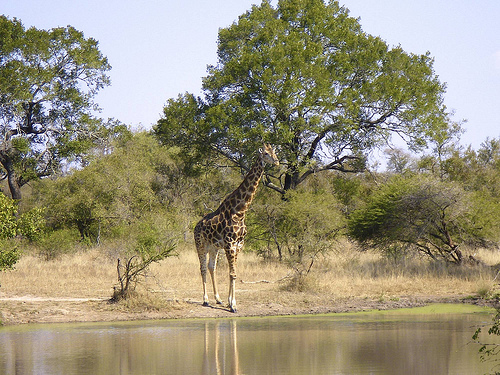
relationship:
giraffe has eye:
[192, 145, 282, 314] [264, 151, 268, 155]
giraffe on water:
[192, 145, 282, 314] [32, 321, 492, 372]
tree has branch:
[338, 175, 485, 272] [403, 217, 442, 240]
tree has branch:
[338, 175, 485, 272] [401, 235, 431, 255]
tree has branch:
[338, 175, 485, 272] [440, 211, 454, 239]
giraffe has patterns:
[192, 145, 282, 314] [209, 207, 244, 255]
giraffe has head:
[192, 145, 282, 314] [257, 140, 280, 166]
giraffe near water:
[192, 145, 282, 314] [32, 321, 492, 372]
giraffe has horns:
[192, 145, 282, 314] [252, 139, 282, 153]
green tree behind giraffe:
[148, 0, 459, 200] [192, 145, 282, 314]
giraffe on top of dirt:
[192, 145, 282, 314] [158, 295, 203, 322]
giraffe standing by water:
[192, 145, 282, 314] [0, 311, 499, 373]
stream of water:
[3, 297, 494, 368] [0, 302, 497, 374]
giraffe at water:
[147, 101, 329, 333] [3, 297, 496, 371]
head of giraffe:
[248, 139, 283, 169] [192, 145, 282, 314]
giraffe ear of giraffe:
[252, 145, 266, 154] [192, 145, 282, 314]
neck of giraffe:
[219, 157, 266, 215] [192, 145, 282, 314]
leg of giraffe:
[224, 240, 236, 310] [192, 145, 282, 314]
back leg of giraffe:
[207, 252, 220, 304] [192, 145, 282, 314]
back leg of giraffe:
[196, 250, 210, 305] [192, 145, 282, 314]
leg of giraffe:
[224, 240, 236, 310] [150, 114, 319, 331]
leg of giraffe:
[225, 244, 243, 306] [150, 114, 319, 331]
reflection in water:
[202, 318, 247, 373] [3, 297, 496, 371]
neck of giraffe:
[219, 157, 266, 215] [176, 129, 417, 354]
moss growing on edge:
[3, 299, 497, 329] [3, 283, 493, 323]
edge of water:
[3, 283, 493, 323] [311, 308, 353, 372]